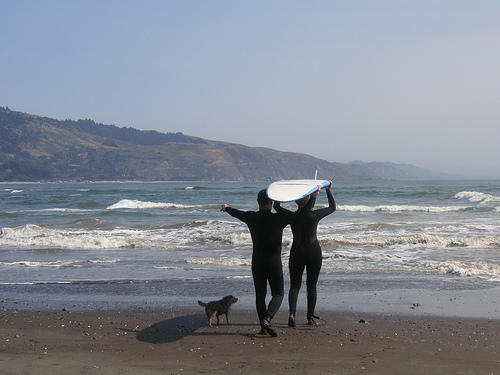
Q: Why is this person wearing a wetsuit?
A: To get warm.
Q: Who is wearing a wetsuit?
A: The woman.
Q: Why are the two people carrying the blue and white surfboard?
A: The surfboard is heavy.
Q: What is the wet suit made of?
A: Rubber and cloth.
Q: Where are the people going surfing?
A: In the ocean.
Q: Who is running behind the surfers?
A: A dog.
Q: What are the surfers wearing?
A: Wetsuits.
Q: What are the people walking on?
A: Sand.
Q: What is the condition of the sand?
A: Wet.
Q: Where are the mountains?
A: Other side of the water.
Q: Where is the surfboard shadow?
A: On the beach.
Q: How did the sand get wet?
A: Splashing ocean waves.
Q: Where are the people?
A: At the beach.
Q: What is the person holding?
A: A surfboard.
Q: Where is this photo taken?
A: Beach.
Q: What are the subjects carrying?
A: Surfboard.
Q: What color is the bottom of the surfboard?
A: White.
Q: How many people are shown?
A: Two.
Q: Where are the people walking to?
A: Water.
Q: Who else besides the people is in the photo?
A: Dog.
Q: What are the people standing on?
A: Sand.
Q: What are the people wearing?
A: Wetsuits.